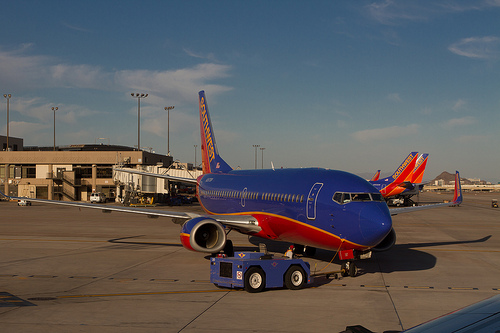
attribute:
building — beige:
[1, 146, 174, 206]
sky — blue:
[151, 7, 273, 39]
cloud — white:
[4, 93, 84, 128]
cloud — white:
[449, 33, 497, 58]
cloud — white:
[113, 55, 234, 110]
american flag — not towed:
[377, 172, 397, 187]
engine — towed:
[176, 213, 229, 254]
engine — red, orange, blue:
[179, 214, 231, 258]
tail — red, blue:
[192, 89, 237, 176]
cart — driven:
[209, 252, 314, 289]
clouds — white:
[91, 67, 163, 112]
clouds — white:
[437, 27, 469, 104]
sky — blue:
[282, 77, 334, 169]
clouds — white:
[57, 60, 222, 87]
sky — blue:
[268, 42, 405, 103]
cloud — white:
[1, 57, 240, 143]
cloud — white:
[0, 92, 99, 140]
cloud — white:
[444, 22, 499, 63]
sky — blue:
[0, 1, 497, 195]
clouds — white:
[1, 42, 230, 154]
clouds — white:
[159, 41, 280, 119]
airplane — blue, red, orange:
[69, 108, 460, 328]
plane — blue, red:
[4, 88, 461, 276]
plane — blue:
[1, 82, 408, 281]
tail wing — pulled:
[195, 90, 226, 176]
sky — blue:
[263, 25, 422, 107]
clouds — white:
[3, 42, 239, 109]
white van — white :
[85, 191, 109, 201]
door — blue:
[301, 179, 329, 224]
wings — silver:
[19, 155, 203, 239]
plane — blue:
[108, 65, 458, 305]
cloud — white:
[308, 21, 488, 161]